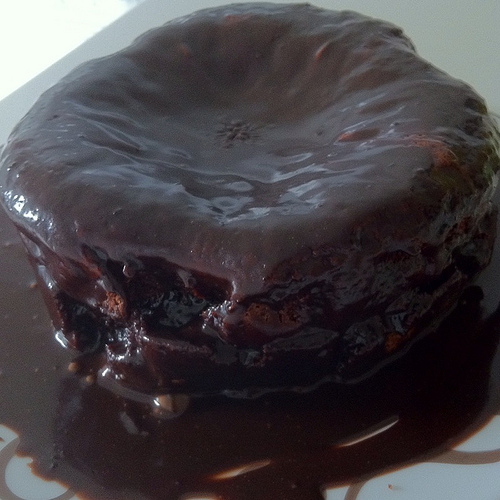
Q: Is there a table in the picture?
A: Yes, there is a table.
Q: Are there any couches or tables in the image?
A: Yes, there is a table.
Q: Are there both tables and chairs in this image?
A: No, there is a table but no chairs.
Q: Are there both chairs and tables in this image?
A: No, there is a table but no chairs.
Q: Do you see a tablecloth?
A: No, there are no tablecloths.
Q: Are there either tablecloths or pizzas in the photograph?
A: No, there are no tablecloths or pizzas.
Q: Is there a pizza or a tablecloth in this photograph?
A: No, there are no tablecloths or pizzas.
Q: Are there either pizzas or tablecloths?
A: No, there are no tablecloths or pizzas.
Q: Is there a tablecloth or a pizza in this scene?
A: No, there are no tablecloths or pizzas.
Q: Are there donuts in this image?
A: No, there are no donuts.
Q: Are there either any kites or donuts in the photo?
A: No, there are no donuts or kites.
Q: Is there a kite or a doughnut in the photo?
A: No, there are no donuts or kites.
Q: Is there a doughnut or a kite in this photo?
A: No, there are no donuts or kites.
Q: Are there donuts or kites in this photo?
A: No, there are no donuts or kites.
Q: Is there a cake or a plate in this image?
A: Yes, there is a cake.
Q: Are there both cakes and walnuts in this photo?
A: No, there is a cake but no walnuts.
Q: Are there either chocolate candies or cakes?
A: Yes, there is a chocolate cake.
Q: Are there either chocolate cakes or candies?
A: Yes, there is a chocolate cake.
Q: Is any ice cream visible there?
A: No, there is no ice cream.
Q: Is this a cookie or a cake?
A: This is a cake.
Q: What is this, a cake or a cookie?
A: This is a cake.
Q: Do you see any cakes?
A: Yes, there is a cake.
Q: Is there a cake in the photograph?
A: Yes, there is a cake.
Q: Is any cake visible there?
A: Yes, there is a cake.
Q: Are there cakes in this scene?
A: Yes, there is a cake.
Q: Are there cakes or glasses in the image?
A: Yes, there is a cake.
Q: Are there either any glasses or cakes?
A: Yes, there is a cake.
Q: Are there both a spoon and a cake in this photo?
A: No, there is a cake but no spoons.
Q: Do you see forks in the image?
A: No, there are no forks.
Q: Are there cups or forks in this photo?
A: No, there are no forks or cups.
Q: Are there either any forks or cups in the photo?
A: No, there are no forks or cups.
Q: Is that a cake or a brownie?
A: That is a cake.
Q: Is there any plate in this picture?
A: Yes, there is a plate.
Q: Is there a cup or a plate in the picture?
A: Yes, there is a plate.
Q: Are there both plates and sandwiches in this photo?
A: No, there is a plate but no sandwiches.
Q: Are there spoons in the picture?
A: No, there are no spoons.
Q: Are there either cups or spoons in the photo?
A: No, there are no spoons or cups.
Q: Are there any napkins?
A: No, there are no napkins.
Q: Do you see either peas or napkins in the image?
A: No, there are no napkins or peas.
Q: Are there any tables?
A: Yes, there is a table.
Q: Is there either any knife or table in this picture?
A: Yes, there is a table.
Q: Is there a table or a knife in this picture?
A: Yes, there is a table.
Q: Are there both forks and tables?
A: No, there is a table but no forks.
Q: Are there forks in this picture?
A: No, there are no forks.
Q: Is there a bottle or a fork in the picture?
A: No, there are no forks or bottles.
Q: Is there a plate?
A: Yes, there is a plate.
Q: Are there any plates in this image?
A: Yes, there is a plate.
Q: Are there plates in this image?
A: Yes, there is a plate.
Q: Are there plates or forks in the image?
A: Yes, there is a plate.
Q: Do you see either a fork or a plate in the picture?
A: Yes, there is a plate.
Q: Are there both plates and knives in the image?
A: No, there is a plate but no knives.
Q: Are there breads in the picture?
A: No, there are no breads.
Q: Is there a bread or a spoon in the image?
A: No, there are no breads or spoons.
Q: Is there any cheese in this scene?
A: No, there is no cheese.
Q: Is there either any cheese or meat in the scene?
A: No, there are no cheese or meat.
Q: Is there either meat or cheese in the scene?
A: No, there are no cheese or meat.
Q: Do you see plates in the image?
A: Yes, there is a plate.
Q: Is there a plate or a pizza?
A: Yes, there is a plate.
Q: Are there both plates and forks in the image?
A: No, there is a plate but no forks.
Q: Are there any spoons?
A: No, there are no spoons.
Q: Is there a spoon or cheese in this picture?
A: No, there are no spoons or cheese.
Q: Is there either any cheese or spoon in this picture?
A: No, there are no spoons or cheese.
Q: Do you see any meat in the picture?
A: No, there is no meat.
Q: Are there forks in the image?
A: No, there are no forks.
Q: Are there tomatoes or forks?
A: No, there are no forks or tomatoes.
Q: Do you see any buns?
A: No, there are no buns.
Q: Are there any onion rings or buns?
A: No, there are no buns or onion rings.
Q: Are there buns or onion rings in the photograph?
A: No, there are no buns or onion rings.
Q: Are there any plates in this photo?
A: Yes, there is a plate.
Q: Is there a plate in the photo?
A: Yes, there is a plate.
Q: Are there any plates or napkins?
A: Yes, there is a plate.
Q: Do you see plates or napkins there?
A: Yes, there is a plate.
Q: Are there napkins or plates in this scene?
A: Yes, there is a plate.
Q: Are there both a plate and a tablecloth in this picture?
A: No, there is a plate but no tablecloths.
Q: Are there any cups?
A: No, there are no cups.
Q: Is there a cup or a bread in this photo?
A: No, there are no cups or breads.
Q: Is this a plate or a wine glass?
A: This is a plate.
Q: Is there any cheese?
A: No, there is no cheese.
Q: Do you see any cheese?
A: No, there is no cheese.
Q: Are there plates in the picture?
A: Yes, there is a plate.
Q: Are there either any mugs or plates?
A: Yes, there is a plate.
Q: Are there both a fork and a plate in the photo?
A: No, there is a plate but no forks.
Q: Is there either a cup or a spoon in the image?
A: No, there are no cups or spoons.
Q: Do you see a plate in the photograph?
A: Yes, there is a plate.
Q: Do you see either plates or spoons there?
A: Yes, there is a plate.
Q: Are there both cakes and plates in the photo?
A: Yes, there are both a plate and a cake.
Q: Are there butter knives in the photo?
A: No, there are no butter knives.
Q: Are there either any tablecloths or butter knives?
A: No, there are no butter knives or tablecloths.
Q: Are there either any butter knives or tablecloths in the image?
A: No, there are no butter knives or tablecloths.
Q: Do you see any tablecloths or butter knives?
A: No, there are no butter knives or tablecloths.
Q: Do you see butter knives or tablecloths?
A: No, there are no butter knives or tablecloths.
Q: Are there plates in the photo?
A: Yes, there is a plate.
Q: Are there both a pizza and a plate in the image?
A: No, there is a plate but no pizzas.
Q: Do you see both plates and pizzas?
A: No, there is a plate but no pizzas.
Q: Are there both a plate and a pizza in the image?
A: No, there is a plate but no pizzas.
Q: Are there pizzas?
A: No, there are no pizzas.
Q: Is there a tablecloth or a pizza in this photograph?
A: No, there are no pizzas or tablecloths.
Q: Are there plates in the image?
A: Yes, there is a plate.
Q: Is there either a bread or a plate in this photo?
A: Yes, there is a plate.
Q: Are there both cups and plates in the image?
A: No, there is a plate but no cups.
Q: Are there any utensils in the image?
A: No, there are no utensils.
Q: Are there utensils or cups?
A: No, there are no utensils or cups.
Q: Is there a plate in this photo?
A: Yes, there is a plate.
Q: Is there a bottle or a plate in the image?
A: Yes, there is a plate.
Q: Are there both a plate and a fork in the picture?
A: No, there is a plate but no forks.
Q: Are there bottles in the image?
A: No, there are no bottles.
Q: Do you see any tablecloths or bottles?
A: No, there are no bottles or tablecloths.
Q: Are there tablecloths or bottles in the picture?
A: No, there are no bottles or tablecloths.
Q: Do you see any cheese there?
A: No, there is no cheese.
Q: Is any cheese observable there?
A: No, there is no cheese.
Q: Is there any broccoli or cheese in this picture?
A: No, there are no cheese or broccoli.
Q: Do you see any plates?
A: Yes, there is a plate.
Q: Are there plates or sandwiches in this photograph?
A: Yes, there is a plate.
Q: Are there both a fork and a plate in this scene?
A: No, there is a plate but no forks.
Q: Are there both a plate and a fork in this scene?
A: No, there is a plate but no forks.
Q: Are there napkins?
A: No, there are no napkins.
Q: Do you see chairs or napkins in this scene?
A: No, there are no napkins or chairs.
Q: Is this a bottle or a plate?
A: This is a plate.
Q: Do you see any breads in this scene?
A: No, there are no breads.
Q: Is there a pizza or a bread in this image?
A: No, there are no breads or pizzas.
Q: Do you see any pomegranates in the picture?
A: No, there are no pomegranates.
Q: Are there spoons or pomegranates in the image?
A: No, there are no pomegranates or spoons.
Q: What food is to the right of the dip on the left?
A: The food is chocolate.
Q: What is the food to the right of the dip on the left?
A: The food is chocolate.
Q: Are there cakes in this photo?
A: Yes, there is a cake.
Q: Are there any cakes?
A: Yes, there is a cake.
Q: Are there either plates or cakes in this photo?
A: Yes, there is a cake.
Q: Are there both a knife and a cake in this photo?
A: No, there is a cake but no knives.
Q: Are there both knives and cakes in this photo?
A: No, there is a cake but no knives.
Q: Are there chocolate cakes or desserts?
A: Yes, there is a chocolate cake.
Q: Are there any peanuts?
A: No, there are no peanuts.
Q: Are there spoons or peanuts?
A: No, there are no peanuts or spoons.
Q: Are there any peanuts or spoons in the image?
A: No, there are no peanuts or spoons.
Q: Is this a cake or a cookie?
A: This is a cake.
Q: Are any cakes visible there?
A: Yes, there is a cake.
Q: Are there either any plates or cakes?
A: Yes, there is a cake.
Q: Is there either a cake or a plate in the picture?
A: Yes, there is a cake.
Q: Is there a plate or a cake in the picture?
A: Yes, there is a cake.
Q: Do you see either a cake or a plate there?
A: Yes, there is a cake.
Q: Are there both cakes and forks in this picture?
A: No, there is a cake but no forks.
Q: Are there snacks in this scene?
A: No, there are no snacks.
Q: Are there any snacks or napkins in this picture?
A: No, there are no snacks or napkins.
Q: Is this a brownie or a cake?
A: This is a cake.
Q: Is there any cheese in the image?
A: No, there is no cheese.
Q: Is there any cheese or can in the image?
A: No, there are no cheese or cans.